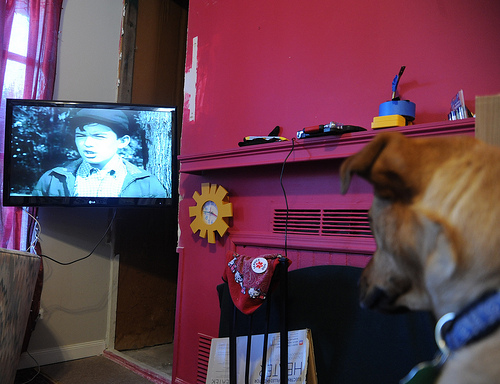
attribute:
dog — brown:
[332, 129, 499, 384]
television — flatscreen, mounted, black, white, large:
[2, 96, 181, 208]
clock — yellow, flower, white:
[186, 181, 239, 247]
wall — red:
[173, 1, 498, 384]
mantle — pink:
[177, 113, 500, 177]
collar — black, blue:
[431, 290, 499, 348]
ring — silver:
[400, 310, 461, 384]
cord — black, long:
[274, 137, 295, 367]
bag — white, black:
[199, 261, 321, 384]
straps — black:
[230, 259, 297, 383]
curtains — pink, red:
[1, 1, 71, 253]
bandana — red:
[221, 252, 292, 315]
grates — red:
[266, 204, 397, 246]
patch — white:
[181, 36, 205, 121]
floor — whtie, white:
[116, 337, 177, 380]